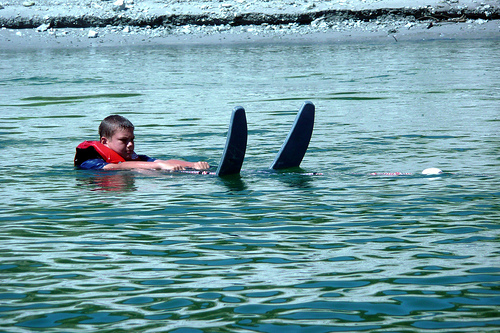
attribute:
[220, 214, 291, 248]
water — surface, rippled, blue, calm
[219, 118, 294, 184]
skis — edge, blue, pointed, up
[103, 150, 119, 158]
life vest — red, curled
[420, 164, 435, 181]
bobber — part, floating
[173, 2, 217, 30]
beach — rocky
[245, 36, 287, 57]
shore — edge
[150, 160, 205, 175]
hands — part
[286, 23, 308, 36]
rock — part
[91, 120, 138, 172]
boy — submerged, concentrated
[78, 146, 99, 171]
vest — red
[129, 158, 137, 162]
shirt — blue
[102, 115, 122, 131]
hair — short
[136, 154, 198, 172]
arms — extended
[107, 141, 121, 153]
skin — pink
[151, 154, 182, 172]
bate — part